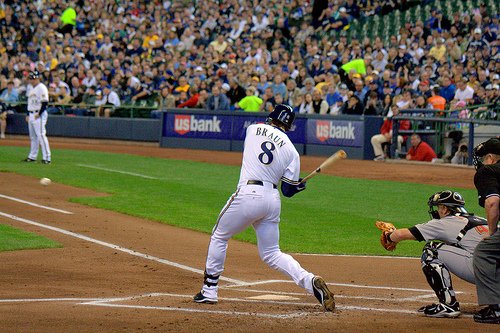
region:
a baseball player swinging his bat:
[185, 92, 362, 307]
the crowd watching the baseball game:
[15, 5, 481, 120]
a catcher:
[374, 173, 494, 325]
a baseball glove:
[374, 215, 400, 254]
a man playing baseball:
[197, 88, 349, 313]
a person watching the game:
[363, 107, 397, 162]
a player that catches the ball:
[18, 63, 57, 167]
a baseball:
[30, 161, 63, 203]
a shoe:
[308, 271, 352, 313]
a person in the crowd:
[238, 80, 271, 120]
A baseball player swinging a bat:
[195, 73, 353, 321]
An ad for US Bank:
[158, 104, 233, 151]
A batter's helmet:
[263, 97, 300, 133]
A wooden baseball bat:
[297, 137, 355, 188]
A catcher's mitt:
[362, 214, 407, 259]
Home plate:
[244, 287, 305, 309]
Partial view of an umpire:
[459, 104, 497, 327]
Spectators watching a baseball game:
[56, 32, 491, 122]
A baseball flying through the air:
[30, 170, 63, 198]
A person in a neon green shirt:
[231, 82, 264, 115]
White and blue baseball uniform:
[223, 103, 345, 325]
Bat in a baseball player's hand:
[296, 144, 366, 212]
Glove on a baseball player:
[376, 216, 405, 250]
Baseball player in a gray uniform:
[388, 181, 498, 289]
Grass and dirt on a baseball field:
[69, 152, 396, 268]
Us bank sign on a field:
[158, 107, 332, 146]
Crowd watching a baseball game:
[154, 36, 396, 119]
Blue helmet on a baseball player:
[260, 99, 322, 143]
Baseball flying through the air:
[29, 173, 54, 188]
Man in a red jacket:
[371, 100, 437, 167]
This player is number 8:
[246, 126, 295, 184]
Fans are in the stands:
[126, 33, 473, 162]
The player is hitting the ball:
[203, 113, 386, 315]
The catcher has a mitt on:
[356, 188, 495, 293]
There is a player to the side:
[21, 73, 87, 192]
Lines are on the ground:
[37, 207, 105, 327]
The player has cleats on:
[301, 258, 361, 330]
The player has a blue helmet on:
[267, 101, 307, 144]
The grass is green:
[152, 162, 279, 267]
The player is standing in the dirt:
[166, 272, 331, 332]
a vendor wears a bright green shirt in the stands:
[57, 3, 86, 30]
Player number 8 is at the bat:
[199, 121, 353, 281]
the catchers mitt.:
[368, 210, 408, 260]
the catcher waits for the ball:
[413, 158, 478, 326]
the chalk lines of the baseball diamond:
[7, 182, 182, 318]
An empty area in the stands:
[327, 0, 475, 65]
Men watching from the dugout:
[365, 101, 493, 178]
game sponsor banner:
[159, 110, 238, 144]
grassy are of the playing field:
[57, 137, 227, 236]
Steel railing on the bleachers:
[57, 95, 164, 130]